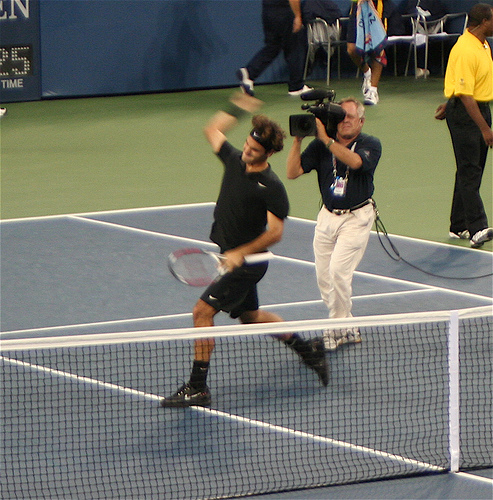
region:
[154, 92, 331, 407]
a man playing tennis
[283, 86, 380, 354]
a man with a video camera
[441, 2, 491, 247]
a man in a yellow shirt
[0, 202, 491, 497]
a blue tennis court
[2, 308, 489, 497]
a white and black tennis net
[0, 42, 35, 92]
a display keeping time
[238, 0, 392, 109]
people walking in the background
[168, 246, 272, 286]
a racket in the man's hand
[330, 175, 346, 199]
a VIP media pass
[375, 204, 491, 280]
a black cable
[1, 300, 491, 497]
net is in photo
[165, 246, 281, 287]
racquet is in photo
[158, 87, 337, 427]
man holding tennis racquet while in motion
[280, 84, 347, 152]
video camera is in the picture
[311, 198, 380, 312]
white pants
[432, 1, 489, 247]
man with yellow shirt and black pants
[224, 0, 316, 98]
person is in motion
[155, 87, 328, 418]
man is wearing black clothing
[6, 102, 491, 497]
court has the colors green and blue on it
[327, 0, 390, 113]
person is in motion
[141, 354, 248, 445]
Black shoe on a foot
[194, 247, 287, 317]
Black shorts on a man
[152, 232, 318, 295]
Tennis racquet in a hand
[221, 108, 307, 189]
Brown hair on a head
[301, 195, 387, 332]
Khaki pants on a man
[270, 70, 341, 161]
Camera in a man's hands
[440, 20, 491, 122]
Yellow shirt on a man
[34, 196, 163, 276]
Blue tennis court with white stripes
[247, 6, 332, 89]
Black pants on a man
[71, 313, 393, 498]
Net on a tennis court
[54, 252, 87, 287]
Blue part of the tennis court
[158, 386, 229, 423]
Mid section of the tennis net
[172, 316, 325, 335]
Top white part of tennis net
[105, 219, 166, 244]
Solid white line on tennis court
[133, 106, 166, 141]
Green part of the tennis court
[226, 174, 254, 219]
Pitch black shirt of tennis player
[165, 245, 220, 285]
Red, white, and black tennis racket of tennis player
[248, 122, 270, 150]
Black nike headband of tennis player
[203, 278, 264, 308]
Black Nike shorts of tennis player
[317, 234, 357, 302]
Khaki pants of camera man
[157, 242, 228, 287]
black and orange tennis racquet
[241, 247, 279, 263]
white tennis racquet handle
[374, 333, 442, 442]
black tennis netting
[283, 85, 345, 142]
large television camera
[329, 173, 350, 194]
identification tag on front of camera man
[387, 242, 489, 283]
black camera power cord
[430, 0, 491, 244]
man in yellow shirt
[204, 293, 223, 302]
company logo on tennis shorts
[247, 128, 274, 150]
black head band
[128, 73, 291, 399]
tennis player celebrating